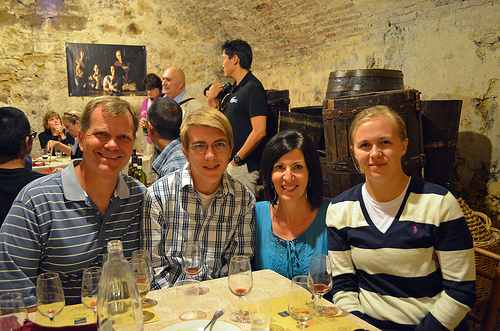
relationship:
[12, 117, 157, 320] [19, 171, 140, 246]
man wears shirt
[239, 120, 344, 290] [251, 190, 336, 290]
woman wears sweater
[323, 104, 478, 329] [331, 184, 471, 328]
girl wears shirt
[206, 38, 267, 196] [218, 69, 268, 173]
man wears shirt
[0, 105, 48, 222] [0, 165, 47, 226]
man wears shirt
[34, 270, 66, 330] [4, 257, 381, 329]
wine glass on table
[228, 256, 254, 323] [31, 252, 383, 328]
glass on table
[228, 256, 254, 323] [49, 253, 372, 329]
glass on table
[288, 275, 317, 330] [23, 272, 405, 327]
glass on table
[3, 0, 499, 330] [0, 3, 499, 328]
restaurant in a rock cave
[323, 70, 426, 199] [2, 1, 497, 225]
barrel against wall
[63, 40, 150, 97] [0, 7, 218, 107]
poster on wall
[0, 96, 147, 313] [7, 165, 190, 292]
man wearing shirt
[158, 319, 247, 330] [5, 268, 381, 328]
plate on table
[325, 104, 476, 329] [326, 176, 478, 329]
girl wearing shirt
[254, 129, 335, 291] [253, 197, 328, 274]
woman wearing shirt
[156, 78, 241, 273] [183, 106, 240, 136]
man has hair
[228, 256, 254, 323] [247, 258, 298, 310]
glass on table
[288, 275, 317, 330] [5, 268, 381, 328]
glass on table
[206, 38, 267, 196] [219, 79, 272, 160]
man in shirt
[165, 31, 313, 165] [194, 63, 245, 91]
man holding camera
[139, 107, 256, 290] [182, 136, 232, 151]
boy wearing glasses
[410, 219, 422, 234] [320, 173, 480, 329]
logo on sweater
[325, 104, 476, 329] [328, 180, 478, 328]
girl wearing sweater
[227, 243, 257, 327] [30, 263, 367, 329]
glass on table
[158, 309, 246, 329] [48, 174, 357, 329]
plate on table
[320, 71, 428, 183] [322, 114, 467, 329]
barrel behind woman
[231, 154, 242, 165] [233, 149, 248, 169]
watch on wrist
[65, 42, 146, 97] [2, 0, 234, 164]
picture on wall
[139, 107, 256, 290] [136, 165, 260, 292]
boy wearing shirt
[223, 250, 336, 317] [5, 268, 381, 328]
glass on table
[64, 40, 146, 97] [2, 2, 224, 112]
picture on wall